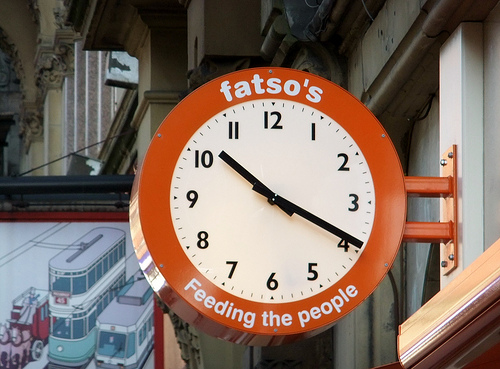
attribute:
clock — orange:
[119, 50, 383, 351]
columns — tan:
[42, 37, 151, 187]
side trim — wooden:
[394, 263, 493, 338]